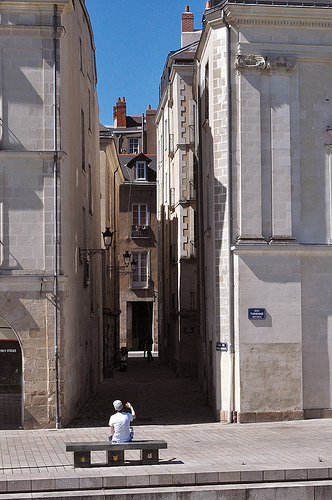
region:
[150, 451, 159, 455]
part of a stand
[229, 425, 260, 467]
part of a floor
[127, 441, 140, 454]
edge of a bencg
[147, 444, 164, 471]
part fo a bench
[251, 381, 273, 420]
part of a wall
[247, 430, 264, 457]
part of a floor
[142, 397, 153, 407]
part of a floor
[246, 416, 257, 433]
part of a floor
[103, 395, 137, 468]
Person sitting on a bench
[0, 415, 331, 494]
Smooth brick stoned walkway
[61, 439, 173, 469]
Long grey concrete bench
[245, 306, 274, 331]
Wall poster with its long shadow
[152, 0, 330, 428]
Tall brick walled building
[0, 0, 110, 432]
Tall brick walled grey building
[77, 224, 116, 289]
Street lamp secured on a wall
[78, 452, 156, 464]
Three brandings on a bench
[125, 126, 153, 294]
Four long windows of a building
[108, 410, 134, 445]
White colored short sleeved shirt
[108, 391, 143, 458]
Person watching while sitting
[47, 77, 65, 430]
Pipe going up side the building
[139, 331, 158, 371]
a person standing between the buildings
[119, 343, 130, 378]
Motorcycle leaning up against the building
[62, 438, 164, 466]
A bench with cut outs on it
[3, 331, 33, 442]
A brown door on the building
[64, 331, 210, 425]
a long passage between the buildings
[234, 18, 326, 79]
Crown molding and intricate work on side of building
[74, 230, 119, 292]
Lanters on building to help with the light at night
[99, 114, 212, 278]
Buildings very close together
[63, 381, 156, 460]
a man is seated down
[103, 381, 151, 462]
he is beckoning someone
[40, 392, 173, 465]
the bench his wooden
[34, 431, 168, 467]
it is brown in color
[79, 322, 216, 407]
the alley is narrow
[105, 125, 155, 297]
the house has windows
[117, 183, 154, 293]
the windows are closed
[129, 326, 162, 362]
a person is in the alley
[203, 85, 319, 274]
the wall is made of bricks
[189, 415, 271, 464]
the pavement has square slabs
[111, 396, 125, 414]
guy is wearing a white hat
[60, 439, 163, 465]
bench do not have a back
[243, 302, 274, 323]
blue sign on the building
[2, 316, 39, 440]
doorway is arch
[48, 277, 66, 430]
pipe is on the building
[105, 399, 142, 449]
man is seating on the bench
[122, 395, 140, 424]
man is pointing straight ahead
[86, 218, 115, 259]
street light on side of building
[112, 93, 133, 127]
red chimney on top of building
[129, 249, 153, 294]
balcony on the building